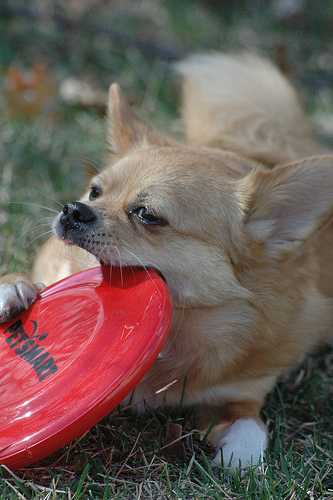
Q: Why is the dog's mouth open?
A: It's chewing.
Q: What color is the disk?
A: Red.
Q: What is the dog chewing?
A: A disk.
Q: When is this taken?
A: During the day.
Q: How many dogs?
A: One.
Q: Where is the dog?
A: On the grass.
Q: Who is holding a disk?
A: Dog.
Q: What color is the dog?
A: Tan.